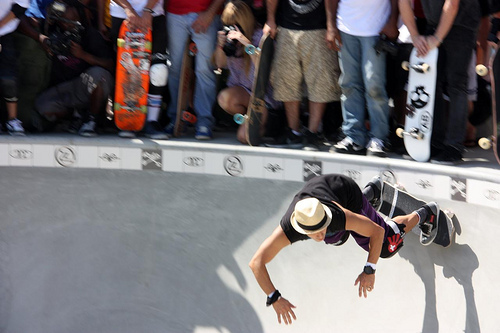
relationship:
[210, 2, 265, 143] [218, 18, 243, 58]
person holds camera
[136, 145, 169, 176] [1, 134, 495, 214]
design on outer edge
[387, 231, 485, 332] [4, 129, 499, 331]
shadow on rink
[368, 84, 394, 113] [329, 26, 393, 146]
dirt spot on jeans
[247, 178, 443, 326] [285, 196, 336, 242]
man wears hat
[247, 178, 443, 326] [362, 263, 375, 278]
man wears watch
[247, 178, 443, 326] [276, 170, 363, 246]
man wears shirt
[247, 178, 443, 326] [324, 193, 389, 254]
man wears purple shorts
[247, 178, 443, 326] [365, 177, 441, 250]
man wears black shoes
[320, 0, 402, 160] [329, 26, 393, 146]
man wears jeans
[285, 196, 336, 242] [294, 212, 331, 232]
hat has black line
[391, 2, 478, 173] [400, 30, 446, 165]
man holding skateboard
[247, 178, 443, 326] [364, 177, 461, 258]
man on skateboard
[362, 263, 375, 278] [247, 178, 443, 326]
watch on man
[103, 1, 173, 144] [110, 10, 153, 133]
person holds skateboard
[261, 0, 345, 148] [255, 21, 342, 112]
person wears tan shorts